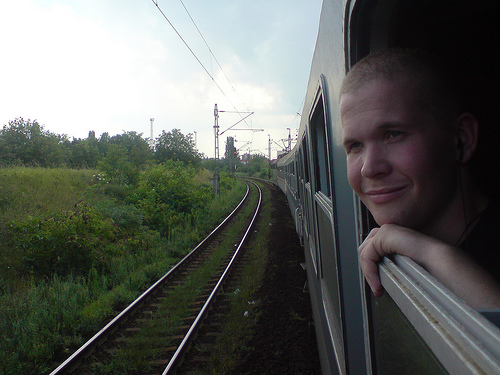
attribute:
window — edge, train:
[346, 0, 497, 331]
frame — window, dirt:
[366, 223, 498, 344]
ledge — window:
[358, 212, 498, 372]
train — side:
[293, 174, 307, 245]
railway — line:
[63, 175, 267, 343]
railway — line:
[266, 0, 493, 373]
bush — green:
[89, 160, 177, 211]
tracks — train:
[142, 200, 294, 364]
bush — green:
[0, 204, 103, 276]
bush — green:
[130, 160, 198, 238]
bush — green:
[96, 146, 152, 209]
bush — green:
[110, 196, 146, 250]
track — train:
[50, 173, 265, 371]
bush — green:
[132, 162, 211, 235]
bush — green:
[12, 200, 128, 270]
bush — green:
[152, 124, 207, 166]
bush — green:
[4, 122, 68, 164]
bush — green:
[65, 128, 107, 161]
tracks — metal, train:
[39, 178, 269, 373]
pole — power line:
[214, 102, 220, 194]